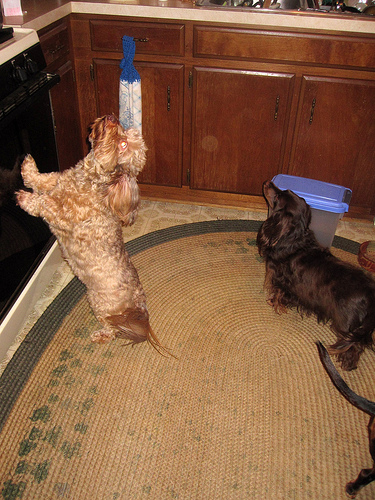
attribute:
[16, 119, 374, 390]
dogs — brown, dark brown, small, light brown, furry, playing, black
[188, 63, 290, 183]
door — wooden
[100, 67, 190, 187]
door — wooden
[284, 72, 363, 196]
door — wooden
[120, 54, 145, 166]
holder — white, blue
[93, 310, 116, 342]
legs — hind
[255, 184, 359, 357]
dog — dark brown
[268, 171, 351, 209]
lid — light blue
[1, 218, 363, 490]
rug — brown and grey, green, tan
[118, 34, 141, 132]
towel — decorative 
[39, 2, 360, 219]
cabinets — dark brown, red wood, brown, Blue and clear, tupperware 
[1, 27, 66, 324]
range — black and white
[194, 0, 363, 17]
sink — stainless steel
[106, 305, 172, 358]
tail — dark brown 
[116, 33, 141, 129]
towel — Blue 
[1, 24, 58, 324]
stove — black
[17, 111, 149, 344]
dog — tan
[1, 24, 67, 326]
stove — black , big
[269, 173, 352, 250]
container — Blue and clear, tupperware , plastic, large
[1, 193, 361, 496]
floor — blue and white, brown, white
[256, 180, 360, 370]
dog — Black and brown, standing 